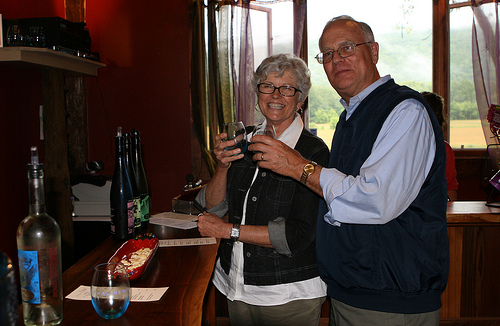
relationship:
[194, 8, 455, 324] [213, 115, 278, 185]
couple drinking wine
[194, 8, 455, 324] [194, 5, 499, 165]
couple standing in front of window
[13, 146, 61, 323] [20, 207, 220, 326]
wine sits on bar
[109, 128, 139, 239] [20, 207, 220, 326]
wine sits on bar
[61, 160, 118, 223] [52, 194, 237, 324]
cash register behind bar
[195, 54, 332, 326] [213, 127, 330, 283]
woman wearing sweater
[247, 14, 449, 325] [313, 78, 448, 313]
man wearing jacket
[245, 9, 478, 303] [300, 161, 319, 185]
man wearing watch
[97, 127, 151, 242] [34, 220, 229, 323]
bottle sitting on a shelf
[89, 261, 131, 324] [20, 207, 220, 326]
glass sitting on a bar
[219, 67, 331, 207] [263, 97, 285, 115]
woman has mouth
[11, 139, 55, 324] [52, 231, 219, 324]
bottle sitting on shelf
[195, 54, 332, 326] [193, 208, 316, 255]
woman has arm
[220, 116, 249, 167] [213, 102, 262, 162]
glass of wine